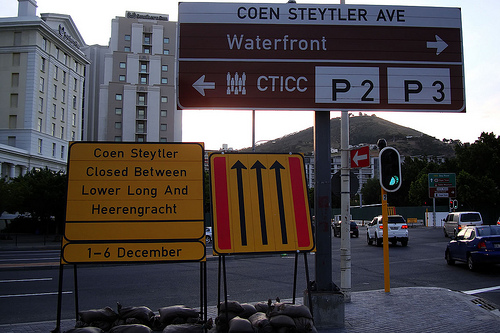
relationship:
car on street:
[445, 224, 500, 271] [0, 220, 499, 325]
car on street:
[441, 209, 483, 237] [0, 220, 499, 325]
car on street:
[365, 214, 410, 246] [0, 220, 499, 325]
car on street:
[335, 220, 359, 238] [0, 220, 499, 325]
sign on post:
[208, 150, 318, 255] [217, 252, 317, 328]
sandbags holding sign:
[69, 296, 318, 332] [57, 139, 207, 264]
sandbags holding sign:
[69, 296, 318, 332] [208, 150, 318, 255]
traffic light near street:
[377, 147, 402, 194] [0, 220, 499, 325]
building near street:
[0, 0, 182, 230] [0, 220, 499, 325]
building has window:
[0, 0, 182, 230] [123, 34, 130, 41]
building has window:
[0, 0, 182, 230] [123, 45, 132, 53]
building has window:
[0, 0, 182, 230] [143, 35, 151, 44]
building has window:
[0, 0, 182, 230] [142, 47, 151, 54]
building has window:
[0, 0, 182, 230] [163, 36, 170, 44]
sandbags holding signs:
[69, 296, 318, 332] [207, 147, 315, 252]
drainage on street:
[455, 281, 484, 322] [384, 237, 490, 286]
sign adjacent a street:
[57, 139, 207, 264] [113, 270, 182, 298]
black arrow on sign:
[265, 153, 293, 243] [57, 139, 207, 264]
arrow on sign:
[350, 142, 378, 177] [342, 140, 377, 172]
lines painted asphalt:
[12, 285, 20, 304] [425, 280, 477, 296]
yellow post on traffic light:
[375, 185, 397, 302] [377, 147, 402, 194]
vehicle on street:
[366, 215, 408, 246] [413, 230, 435, 280]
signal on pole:
[366, 140, 403, 205] [375, 179, 400, 309]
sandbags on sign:
[69, 296, 318, 332] [66, 137, 308, 256]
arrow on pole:
[414, 32, 455, 65] [334, 107, 354, 296]